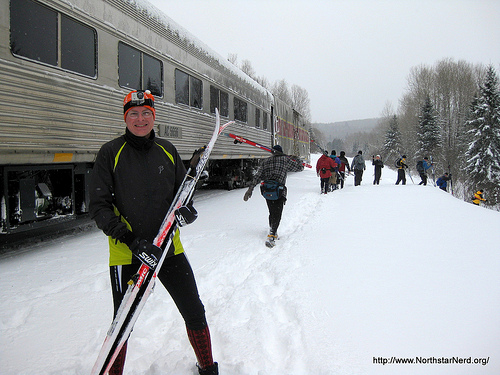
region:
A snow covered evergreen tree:
[459, 63, 499, 207]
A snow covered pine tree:
[463, 66, 498, 208]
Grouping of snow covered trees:
[381, 95, 495, 158]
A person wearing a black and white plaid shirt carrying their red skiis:
[228, 125, 313, 250]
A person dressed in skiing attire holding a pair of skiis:
[70, 82, 237, 374]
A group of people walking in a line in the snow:
[312, 143, 492, 209]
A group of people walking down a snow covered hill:
[313, 133, 495, 209]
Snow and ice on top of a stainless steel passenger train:
[161, 10, 278, 111]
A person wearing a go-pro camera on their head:
[118, 84, 159, 136]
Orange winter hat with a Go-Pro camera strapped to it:
[120, 83, 155, 110]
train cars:
[40, 12, 290, 110]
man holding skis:
[95, 69, 227, 357]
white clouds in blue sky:
[240, 15, 272, 47]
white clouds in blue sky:
[324, 12, 358, 52]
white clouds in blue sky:
[350, 39, 427, 94]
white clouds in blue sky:
[341, 46, 379, 101]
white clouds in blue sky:
[394, 12, 446, 46]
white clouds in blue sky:
[237, 6, 295, 44]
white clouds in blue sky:
[282, 19, 363, 69]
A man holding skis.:
[86, 88, 237, 374]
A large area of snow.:
[1, 149, 499, 373]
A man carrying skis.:
[227, 133, 312, 251]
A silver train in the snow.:
[0, 20, 312, 242]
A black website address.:
[371, 355, 493, 367]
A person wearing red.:
[316, 146, 337, 193]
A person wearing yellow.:
[469, 186, 488, 206]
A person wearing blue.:
[413, 154, 433, 188]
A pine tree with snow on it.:
[454, 60, 499, 209]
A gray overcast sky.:
[150, 0, 499, 123]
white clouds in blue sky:
[288, 12, 349, 43]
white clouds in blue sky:
[370, 15, 435, 45]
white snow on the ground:
[350, 260, 400, 300]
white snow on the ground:
[406, 287, 461, 310]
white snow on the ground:
[266, 265, 392, 350]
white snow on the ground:
[20, 268, 61, 304]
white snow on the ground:
[341, 215, 404, 266]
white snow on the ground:
[245, 292, 295, 342]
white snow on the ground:
[330, 241, 432, 303]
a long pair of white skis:
[88, 112, 231, 370]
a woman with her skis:
[85, 85, 230, 374]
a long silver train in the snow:
[2, 0, 337, 250]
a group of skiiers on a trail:
[75, 94, 497, 371]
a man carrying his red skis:
[222, 125, 312, 243]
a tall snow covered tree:
[458, 80, 499, 203]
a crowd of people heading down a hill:
[316, 145, 452, 197]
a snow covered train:
[273, 96, 314, 158]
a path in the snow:
[231, 245, 317, 372]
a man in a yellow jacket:
[472, 183, 484, 210]